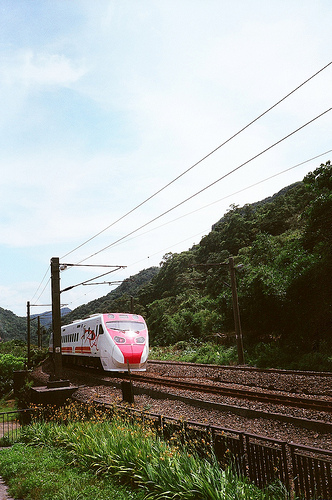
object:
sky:
[4, 0, 332, 144]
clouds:
[0, 0, 331, 95]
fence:
[0, 399, 332, 499]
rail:
[108, 365, 332, 433]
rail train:
[155, 371, 332, 422]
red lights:
[102, 312, 147, 364]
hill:
[167, 160, 332, 371]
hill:
[0, 306, 75, 359]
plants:
[22, 391, 302, 500]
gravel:
[148, 372, 331, 458]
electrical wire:
[58, 57, 331, 265]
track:
[240, 397, 310, 430]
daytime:
[0, 0, 329, 422]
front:
[100, 311, 149, 373]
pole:
[50, 257, 63, 379]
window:
[105, 321, 145, 331]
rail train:
[49, 312, 149, 371]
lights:
[134, 336, 147, 343]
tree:
[235, 160, 332, 346]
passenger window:
[62, 331, 80, 343]